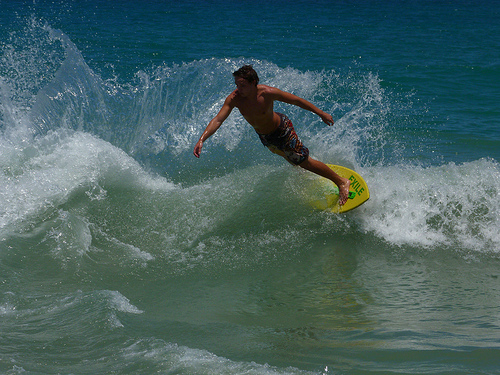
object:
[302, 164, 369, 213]
surf board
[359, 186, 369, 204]
tip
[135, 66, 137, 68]
water drop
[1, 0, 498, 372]
ocean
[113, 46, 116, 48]
drop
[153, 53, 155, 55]
water drop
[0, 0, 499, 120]
air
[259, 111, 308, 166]
swimming trunks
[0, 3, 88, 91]
water drops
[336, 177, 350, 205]
legs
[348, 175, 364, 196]
decal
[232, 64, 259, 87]
brown hair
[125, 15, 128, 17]
water drop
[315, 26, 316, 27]
water drop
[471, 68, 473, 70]
water drop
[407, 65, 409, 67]
water drop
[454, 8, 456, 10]
water drop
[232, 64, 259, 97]
head surfer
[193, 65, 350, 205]
man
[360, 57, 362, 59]
drop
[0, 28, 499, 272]
wave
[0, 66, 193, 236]
deep water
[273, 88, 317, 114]
arm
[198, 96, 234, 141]
arm